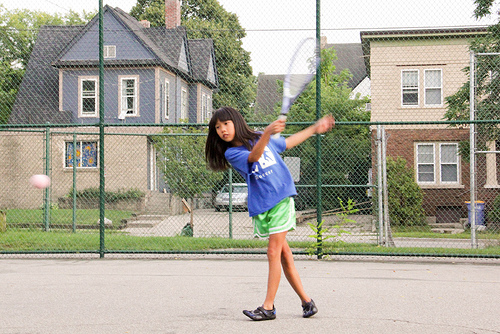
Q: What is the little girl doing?
A: Playing tennis.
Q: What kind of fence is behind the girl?
A: Chain link.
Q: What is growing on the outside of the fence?
A: Grass.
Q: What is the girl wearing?
A: Shirt and shorts.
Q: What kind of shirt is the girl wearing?
A: T Shirt.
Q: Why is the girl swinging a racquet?
A: To hit the ball.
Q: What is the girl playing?
A: Tennis.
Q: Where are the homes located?
A: Behind a fence.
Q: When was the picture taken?
A: During a tennis game.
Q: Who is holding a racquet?
A: A girl.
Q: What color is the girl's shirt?
A: Blue.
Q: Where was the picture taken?
A: Tennis court.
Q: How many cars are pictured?
A: 1.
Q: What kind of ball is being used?
A: Tennis ball.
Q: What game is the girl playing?
A: Tennis.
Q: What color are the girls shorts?
A: Green.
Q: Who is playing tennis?
A: A girl.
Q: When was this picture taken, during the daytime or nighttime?
A: Daytime.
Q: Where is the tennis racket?
A: Her right hand.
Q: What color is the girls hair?
A: Brown.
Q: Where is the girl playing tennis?
A: Tennis court.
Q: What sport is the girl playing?
A: Tennis.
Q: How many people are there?
A: One.